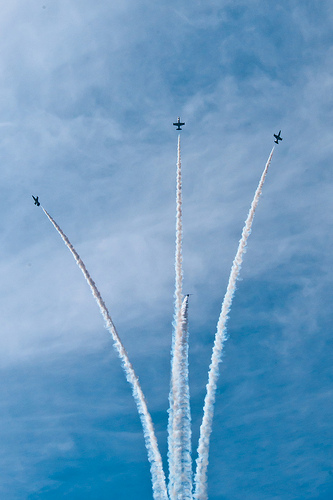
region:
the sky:
[50, 380, 168, 499]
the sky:
[244, 378, 277, 475]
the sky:
[272, 388, 289, 491]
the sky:
[251, 409, 268, 494]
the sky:
[234, 415, 263, 495]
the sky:
[267, 395, 281, 478]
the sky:
[254, 425, 264, 486]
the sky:
[282, 391, 293, 489]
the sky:
[253, 395, 272, 472]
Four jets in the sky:
[18, 107, 305, 316]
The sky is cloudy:
[9, 56, 320, 350]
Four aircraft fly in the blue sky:
[16, 109, 324, 489]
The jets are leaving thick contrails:
[43, 141, 287, 494]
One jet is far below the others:
[182, 288, 198, 303]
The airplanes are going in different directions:
[21, 108, 297, 345]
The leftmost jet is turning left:
[28, 192, 42, 206]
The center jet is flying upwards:
[166, 113, 192, 133]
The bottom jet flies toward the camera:
[181, 289, 196, 306]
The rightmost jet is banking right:
[267, 126, 290, 149]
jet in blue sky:
[165, 114, 193, 136]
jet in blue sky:
[24, 193, 44, 211]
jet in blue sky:
[265, 130, 292, 150]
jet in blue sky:
[183, 291, 192, 297]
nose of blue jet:
[175, 116, 183, 121]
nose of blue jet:
[275, 127, 284, 133]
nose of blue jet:
[29, 192, 34, 198]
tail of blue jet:
[37, 202, 45, 211]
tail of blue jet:
[176, 127, 183, 132]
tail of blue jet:
[269, 138, 278, 146]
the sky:
[292, 430, 319, 485]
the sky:
[240, 484, 247, 493]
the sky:
[250, 456, 272, 494]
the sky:
[223, 448, 255, 491]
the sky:
[255, 428, 290, 495]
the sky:
[237, 450, 275, 498]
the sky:
[245, 437, 261, 475]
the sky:
[232, 450, 242, 498]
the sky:
[30, 370, 108, 495]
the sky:
[68, 416, 119, 486]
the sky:
[101, 449, 147, 489]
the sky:
[78, 399, 166, 471]